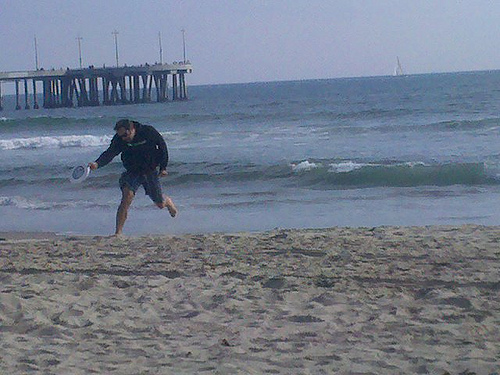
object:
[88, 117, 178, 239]
man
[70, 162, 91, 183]
frisbee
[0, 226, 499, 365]
sand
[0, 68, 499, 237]
water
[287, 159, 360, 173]
ripples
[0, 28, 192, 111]
pier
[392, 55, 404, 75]
sail boat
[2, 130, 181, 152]
wave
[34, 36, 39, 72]
pole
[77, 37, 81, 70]
pole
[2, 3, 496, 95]
sky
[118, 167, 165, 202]
shorts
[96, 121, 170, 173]
hoodie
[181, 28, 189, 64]
pole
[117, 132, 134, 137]
sunglasses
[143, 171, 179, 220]
left leg